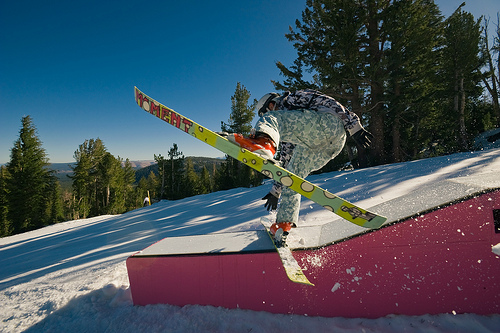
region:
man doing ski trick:
[123, 71, 437, 301]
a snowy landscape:
[30, 21, 496, 331]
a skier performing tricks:
[41, 51, 498, 331]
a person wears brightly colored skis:
[84, 59, 439, 275]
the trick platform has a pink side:
[108, 191, 498, 328]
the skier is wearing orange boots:
[58, 57, 497, 258]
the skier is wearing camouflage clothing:
[95, 54, 487, 289]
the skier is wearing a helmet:
[81, 64, 498, 301]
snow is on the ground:
[13, 55, 490, 329]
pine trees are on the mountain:
[10, 46, 470, 213]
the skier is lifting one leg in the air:
[95, 46, 497, 311]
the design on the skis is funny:
[116, 82, 411, 289]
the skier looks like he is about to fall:
[112, 67, 412, 302]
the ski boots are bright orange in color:
[201, 92, 308, 260]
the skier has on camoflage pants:
[210, 63, 365, 250]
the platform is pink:
[112, 157, 499, 330]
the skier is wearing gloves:
[332, 117, 387, 164]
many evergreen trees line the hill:
[11, 17, 499, 262]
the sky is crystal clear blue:
[37, 21, 190, 71]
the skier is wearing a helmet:
[242, 87, 282, 116]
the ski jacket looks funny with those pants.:
[245, 89, 381, 149]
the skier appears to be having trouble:
[98, 47, 439, 272]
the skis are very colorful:
[103, 42, 385, 267]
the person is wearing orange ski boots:
[218, 115, 292, 165]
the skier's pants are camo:
[229, 90, 344, 243]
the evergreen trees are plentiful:
[8, 105, 225, 231]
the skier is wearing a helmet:
[242, 82, 302, 124]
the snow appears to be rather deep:
[9, 234, 64, 299]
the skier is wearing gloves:
[226, 76, 396, 258]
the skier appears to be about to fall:
[102, 71, 497, 321]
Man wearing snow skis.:
[131, 85, 382, 285]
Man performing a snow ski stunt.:
[125, 80, 495, 315]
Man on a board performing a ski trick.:
[125, 80, 495, 310]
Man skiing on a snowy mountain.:
[0, 85, 495, 327]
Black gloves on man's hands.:
[260, 125, 375, 206]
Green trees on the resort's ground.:
[0, 115, 140, 230]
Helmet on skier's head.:
[255, 85, 277, 116]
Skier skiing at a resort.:
[7, 15, 492, 320]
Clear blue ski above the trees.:
[21, 10, 256, 75]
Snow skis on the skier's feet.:
[131, 85, 386, 285]